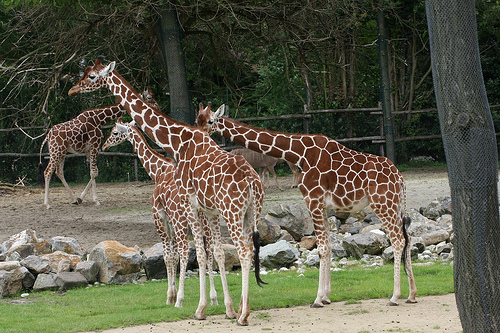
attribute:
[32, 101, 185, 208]
giraffe — spotted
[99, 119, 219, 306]
giraffe — three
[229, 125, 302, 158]
neck — spotted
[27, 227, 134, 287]
rocks — gray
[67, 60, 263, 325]
giraffe — spotted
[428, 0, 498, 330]
tree trunk — spotted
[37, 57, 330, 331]
giraffe — spotted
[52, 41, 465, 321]
giraffes — three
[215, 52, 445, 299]
giraffe — spotted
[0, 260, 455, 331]
grass — green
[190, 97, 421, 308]
giraffe — four, dirt,  brown and beige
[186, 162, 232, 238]
spots — dark brown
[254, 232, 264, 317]
hair — black